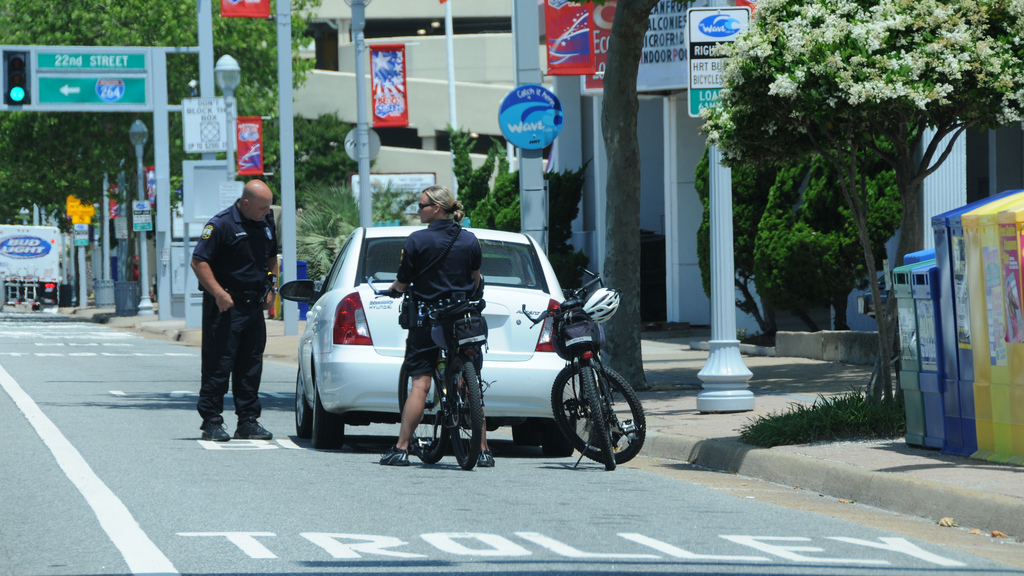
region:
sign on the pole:
[687, 85, 746, 114]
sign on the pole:
[684, 63, 727, 83]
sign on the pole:
[668, 47, 746, 64]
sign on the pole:
[675, 0, 740, 57]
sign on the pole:
[522, 7, 596, 68]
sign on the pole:
[490, 72, 588, 165]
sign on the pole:
[378, 51, 408, 122]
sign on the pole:
[226, 123, 280, 172]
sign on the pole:
[213, 0, 278, 29]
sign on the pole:
[39, 54, 142, 100]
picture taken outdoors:
[14, 14, 1005, 572]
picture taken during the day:
[30, 17, 1020, 533]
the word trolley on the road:
[178, 526, 975, 572]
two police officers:
[176, 104, 515, 441]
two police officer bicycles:
[391, 258, 680, 478]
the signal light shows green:
[4, 50, 31, 107]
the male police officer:
[194, 164, 296, 433]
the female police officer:
[383, 157, 482, 456]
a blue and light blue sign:
[497, 80, 567, 163]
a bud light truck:
[10, 221, 55, 295]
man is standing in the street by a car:
[161, 177, 297, 449]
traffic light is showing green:
[5, 40, 35, 105]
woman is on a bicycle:
[387, 189, 509, 478]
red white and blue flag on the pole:
[356, 37, 430, 135]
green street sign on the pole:
[22, 41, 155, 117]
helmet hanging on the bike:
[583, 269, 618, 327]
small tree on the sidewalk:
[754, 29, 941, 407]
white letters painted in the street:
[196, 508, 964, 573]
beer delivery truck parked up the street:
[6, 222, 74, 298]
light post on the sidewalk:
[115, 107, 170, 326]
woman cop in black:
[359, 175, 495, 460]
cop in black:
[172, 178, 281, 438]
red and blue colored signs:
[231, 108, 260, 173]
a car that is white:
[301, 201, 599, 476]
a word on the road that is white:
[201, 508, 920, 572]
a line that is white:
[43, 423, 160, 569]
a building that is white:
[362, 28, 578, 197]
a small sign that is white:
[672, 19, 753, 103]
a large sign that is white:
[590, 19, 739, 118]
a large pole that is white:
[669, 124, 768, 439]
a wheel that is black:
[275, 376, 353, 457]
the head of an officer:
[409, 165, 467, 241]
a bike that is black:
[503, 288, 655, 475]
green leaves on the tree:
[792, 200, 830, 273]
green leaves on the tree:
[792, 235, 830, 293]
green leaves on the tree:
[874, 159, 903, 237]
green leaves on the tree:
[751, 124, 759, 182]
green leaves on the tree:
[763, 42, 795, 126]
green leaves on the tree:
[845, 19, 909, 103]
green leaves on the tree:
[933, 16, 976, 89]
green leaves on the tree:
[789, 34, 832, 89]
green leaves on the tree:
[310, 113, 327, 151]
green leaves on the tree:
[105, 7, 143, 36]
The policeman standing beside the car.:
[176, 170, 290, 442]